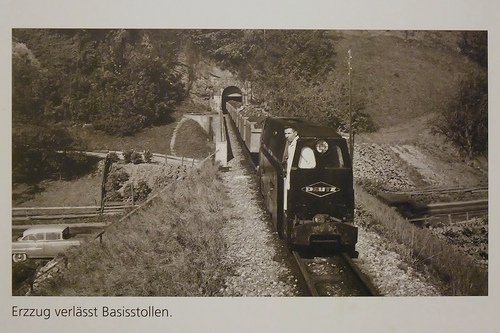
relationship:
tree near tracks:
[423, 62, 495, 166] [274, 239, 394, 301]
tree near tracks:
[0, 150, 86, 178] [274, 239, 394, 301]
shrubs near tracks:
[378, 178, 427, 276] [274, 239, 394, 301]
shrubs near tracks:
[144, 160, 226, 272] [274, 239, 394, 301]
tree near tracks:
[55, 48, 177, 118] [274, 239, 394, 301]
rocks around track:
[242, 232, 270, 261] [289, 262, 372, 285]